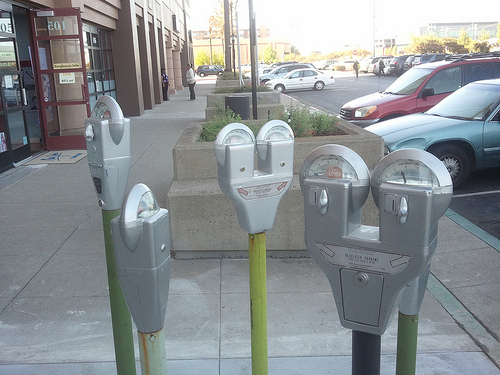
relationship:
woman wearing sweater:
[182, 59, 200, 103] [183, 67, 199, 87]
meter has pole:
[212, 117, 298, 237] [244, 231, 273, 374]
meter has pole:
[298, 141, 456, 338] [348, 328, 384, 374]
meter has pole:
[108, 179, 174, 336] [136, 325, 171, 374]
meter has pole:
[81, 92, 136, 215] [100, 205, 139, 374]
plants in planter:
[200, 101, 343, 141] [165, 112, 389, 266]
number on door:
[45, 17, 68, 35] [13, 5, 93, 157]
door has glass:
[13, 5, 93, 157] [32, 15, 91, 141]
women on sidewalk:
[157, 62, 201, 102] [2, 69, 497, 372]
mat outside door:
[15, 145, 91, 169] [13, 5, 93, 157]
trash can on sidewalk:
[221, 92, 254, 125] [2, 69, 497, 372]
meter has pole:
[394, 256, 434, 317] [394, 310, 422, 374]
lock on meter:
[350, 266, 375, 287] [298, 141, 456, 338]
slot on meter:
[307, 183, 322, 210] [298, 141, 456, 338]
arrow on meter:
[399, 168, 409, 184] [298, 141, 456, 338]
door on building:
[13, 5, 93, 157] [0, 1, 196, 175]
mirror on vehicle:
[420, 84, 436, 103] [334, 49, 499, 130]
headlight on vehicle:
[351, 102, 380, 121] [334, 49, 499, 130]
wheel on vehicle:
[427, 139, 475, 193] [362, 75, 499, 197]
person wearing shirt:
[182, 59, 200, 103] [183, 67, 199, 87]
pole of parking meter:
[348, 328, 384, 374] [298, 141, 456, 338]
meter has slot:
[298, 141, 456, 338] [383, 191, 400, 216]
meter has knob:
[298, 141, 456, 338] [315, 186, 331, 217]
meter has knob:
[298, 141, 456, 338] [394, 192, 410, 225]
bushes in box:
[200, 101, 343, 141] [165, 112, 389, 266]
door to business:
[13, 5, 93, 157] [0, 1, 122, 180]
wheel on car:
[310, 78, 330, 94] [263, 66, 338, 96]